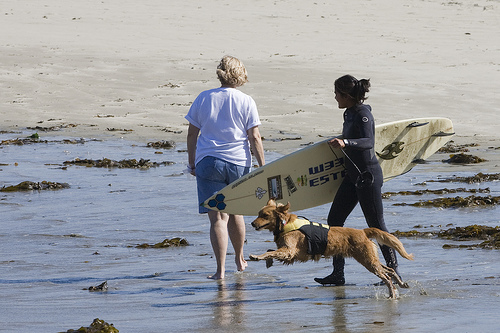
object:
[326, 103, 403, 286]
wetsuit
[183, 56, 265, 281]
lady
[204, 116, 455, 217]
surfboard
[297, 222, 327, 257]
jacket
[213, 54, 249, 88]
blonde hair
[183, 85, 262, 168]
t shirt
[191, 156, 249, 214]
denim shorts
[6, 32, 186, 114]
stormy seas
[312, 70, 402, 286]
lady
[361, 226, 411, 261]
bushy tail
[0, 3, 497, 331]
beach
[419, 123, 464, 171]
ground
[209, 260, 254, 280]
barefoot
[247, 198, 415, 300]
dog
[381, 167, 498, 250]
seaweed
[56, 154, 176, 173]
seaweed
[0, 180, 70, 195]
seaweed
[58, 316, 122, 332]
seaweed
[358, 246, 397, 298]
leg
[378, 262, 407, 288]
leg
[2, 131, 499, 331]
water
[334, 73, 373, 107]
hair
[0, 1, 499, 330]
sand